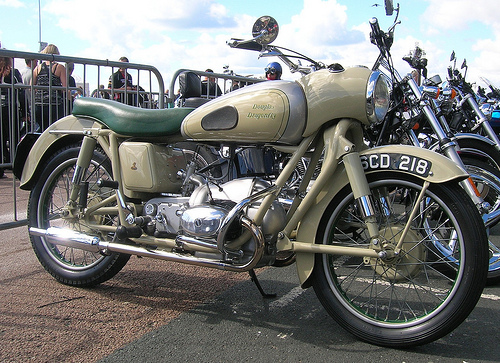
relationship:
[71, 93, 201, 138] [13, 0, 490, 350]
green seat of motorcycle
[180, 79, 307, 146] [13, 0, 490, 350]
tank of motorcycle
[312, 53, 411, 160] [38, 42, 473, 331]
headlight of motorcycle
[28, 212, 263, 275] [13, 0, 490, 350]
muffler of motorcycle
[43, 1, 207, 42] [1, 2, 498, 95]
cloud in sky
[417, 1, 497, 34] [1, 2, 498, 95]
cloud in sky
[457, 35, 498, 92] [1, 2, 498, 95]
cloud in sky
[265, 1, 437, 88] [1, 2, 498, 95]
cloud in sky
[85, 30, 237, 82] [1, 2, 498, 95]
cloud in sky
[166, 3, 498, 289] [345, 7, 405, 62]
motorcycle has handlebar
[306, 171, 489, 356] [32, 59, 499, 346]
tire on front of motorcycle